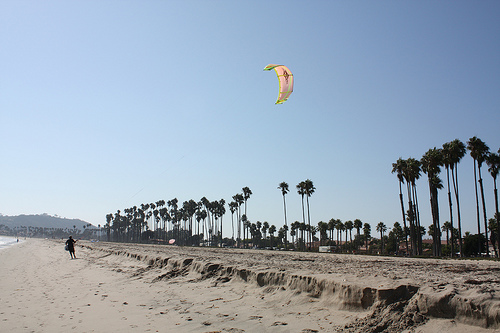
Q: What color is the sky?
A: Blue.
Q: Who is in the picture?
A: A man.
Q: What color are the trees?
A: Green.